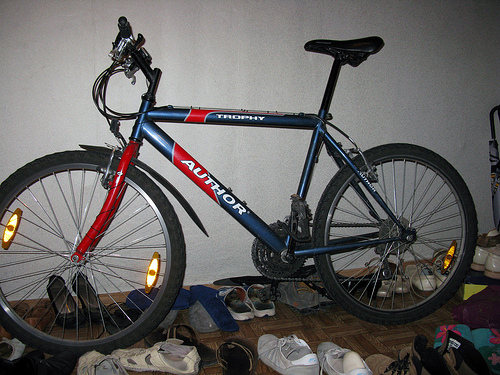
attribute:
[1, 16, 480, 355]
bicycle — red, blue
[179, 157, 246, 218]
lettering — white, all caps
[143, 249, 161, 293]
reflector — yellow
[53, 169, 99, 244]
spokes — silver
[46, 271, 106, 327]
heels — black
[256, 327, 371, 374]
shoes — gray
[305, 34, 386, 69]
seat — black